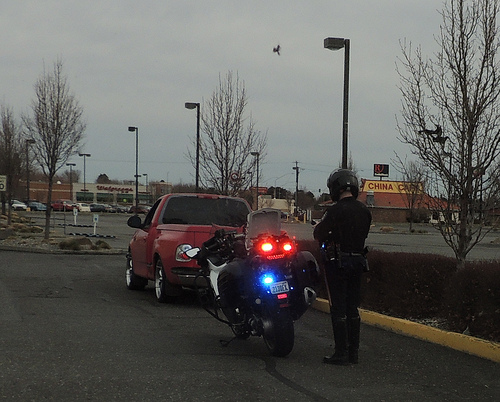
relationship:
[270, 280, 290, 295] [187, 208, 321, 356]
license plate on motorcycle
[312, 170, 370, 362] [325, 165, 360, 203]
police officer wearing helmet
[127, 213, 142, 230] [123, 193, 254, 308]
mirror on truck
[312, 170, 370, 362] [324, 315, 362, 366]
police officer wearing boots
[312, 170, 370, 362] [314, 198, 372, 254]
police officer wearing shirt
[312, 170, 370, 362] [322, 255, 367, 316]
police officer wearing pants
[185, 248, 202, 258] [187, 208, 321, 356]
mirror on motorcycle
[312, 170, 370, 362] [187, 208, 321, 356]
police officer by motorcycle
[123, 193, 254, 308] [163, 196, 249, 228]
truck has rear windshield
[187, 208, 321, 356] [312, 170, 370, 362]
motorcycle belongs to police officer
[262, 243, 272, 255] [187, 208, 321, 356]
light on motorcycle